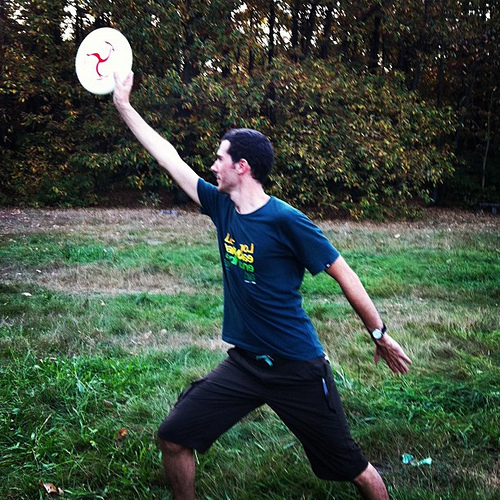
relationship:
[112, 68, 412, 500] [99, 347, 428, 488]
man on grass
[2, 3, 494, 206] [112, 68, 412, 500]
trees behind man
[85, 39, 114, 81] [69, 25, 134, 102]
image on frisbee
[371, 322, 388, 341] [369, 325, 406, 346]
wrist watch on wrist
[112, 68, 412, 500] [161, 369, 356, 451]
man wearing shorts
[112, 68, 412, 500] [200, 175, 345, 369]
man wearing shirt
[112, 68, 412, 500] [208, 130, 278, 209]
man has head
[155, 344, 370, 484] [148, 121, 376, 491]
shorts on man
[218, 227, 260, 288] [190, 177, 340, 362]
image on shirt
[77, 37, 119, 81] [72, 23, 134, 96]
image on frisbee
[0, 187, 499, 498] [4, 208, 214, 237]
ground with grass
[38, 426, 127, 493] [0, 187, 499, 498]
leaves on ground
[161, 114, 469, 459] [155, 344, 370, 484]
man wearing shorts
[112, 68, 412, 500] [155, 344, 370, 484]
man wearing shorts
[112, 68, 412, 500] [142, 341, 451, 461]
man wearing black shorts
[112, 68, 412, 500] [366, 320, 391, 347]
man wearing watch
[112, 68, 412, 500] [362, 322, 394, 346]
man wearing wrist watch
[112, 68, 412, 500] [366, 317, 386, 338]
man wearing wrist watch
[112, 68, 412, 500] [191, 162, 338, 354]
man wearing shirt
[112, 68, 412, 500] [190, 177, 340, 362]
man wearing shirt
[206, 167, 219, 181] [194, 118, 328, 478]
nose of a man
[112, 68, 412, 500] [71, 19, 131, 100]
man with frisbee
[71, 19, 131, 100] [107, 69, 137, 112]
frisbee in hand